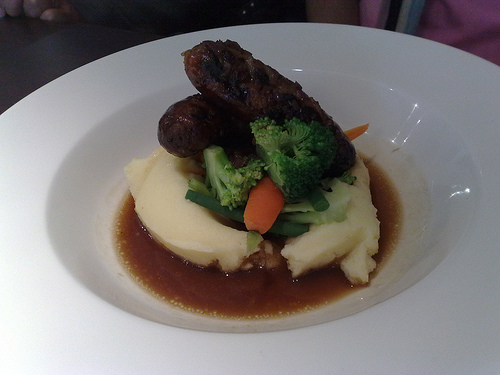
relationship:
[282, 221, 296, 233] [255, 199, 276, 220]
green beans under a carrot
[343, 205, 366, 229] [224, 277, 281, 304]
mashed potatoes in gravy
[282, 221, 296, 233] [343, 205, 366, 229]
green beans on top of mashed potatoes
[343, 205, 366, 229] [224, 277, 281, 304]
mashed potatoes with gravy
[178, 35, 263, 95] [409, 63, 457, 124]
sausage on top of a plate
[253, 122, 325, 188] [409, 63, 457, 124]
steamed brocolli on top of a plate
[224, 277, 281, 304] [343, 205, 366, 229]
gravy under mashed potatoes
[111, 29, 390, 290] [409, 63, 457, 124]
food on top of a plate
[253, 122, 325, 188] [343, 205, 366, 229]
steamed brocolli on top of mashed potatoes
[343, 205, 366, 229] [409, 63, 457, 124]
mashed potatoes on top of a plate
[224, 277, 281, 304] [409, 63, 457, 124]
gravy on top of plate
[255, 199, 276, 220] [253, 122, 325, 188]
carrot in middle of steamed brocolli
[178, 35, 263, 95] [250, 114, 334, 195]
sausage with vegetable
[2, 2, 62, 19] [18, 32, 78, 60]
knuckles on table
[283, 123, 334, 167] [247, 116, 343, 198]
floret on broccoli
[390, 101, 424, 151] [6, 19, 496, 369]
reflection on bowl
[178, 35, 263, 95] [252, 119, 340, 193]
sausage behind broccoli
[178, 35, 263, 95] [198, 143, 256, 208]
sausage behind broccoli